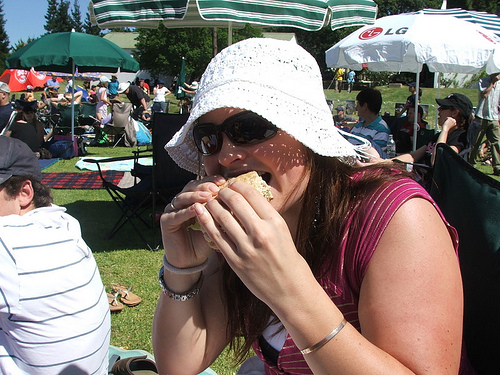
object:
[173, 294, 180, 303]
square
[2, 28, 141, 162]
umbrella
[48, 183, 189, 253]
shadow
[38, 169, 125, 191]
blanket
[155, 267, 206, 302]
wrist watch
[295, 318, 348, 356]
bracelet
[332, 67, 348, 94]
person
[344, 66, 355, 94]
person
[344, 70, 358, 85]
shirt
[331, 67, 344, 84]
shirt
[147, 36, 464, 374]
lady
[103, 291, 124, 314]
sandals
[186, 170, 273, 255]
sandwhich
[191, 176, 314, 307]
hand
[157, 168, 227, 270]
hand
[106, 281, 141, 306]
sandals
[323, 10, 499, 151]
umbrella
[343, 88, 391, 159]
people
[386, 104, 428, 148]
people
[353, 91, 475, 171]
people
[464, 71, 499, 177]
peoples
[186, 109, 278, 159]
glasses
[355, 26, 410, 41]
logo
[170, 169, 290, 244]
woman eating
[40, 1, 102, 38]
tree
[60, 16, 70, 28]
leaves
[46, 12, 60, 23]
branches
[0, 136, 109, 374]
gentleman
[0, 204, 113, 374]
striped shirt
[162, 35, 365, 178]
hat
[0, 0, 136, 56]
sky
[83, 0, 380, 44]
tent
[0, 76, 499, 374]
grass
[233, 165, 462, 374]
shirt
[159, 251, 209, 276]
wristband